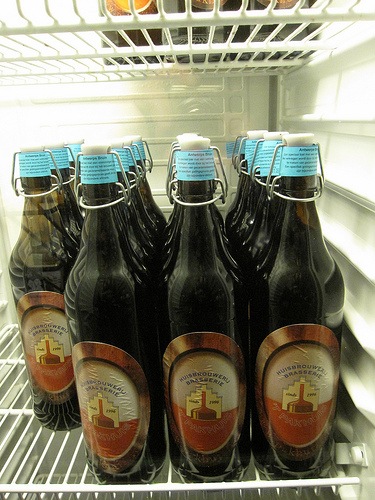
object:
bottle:
[250, 132, 345, 478]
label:
[71, 340, 151, 477]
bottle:
[155, 136, 251, 482]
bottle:
[41, 139, 84, 244]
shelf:
[0, 324, 362, 500]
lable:
[280, 146, 319, 178]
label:
[254, 324, 340, 462]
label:
[15, 290, 75, 405]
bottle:
[8, 146, 83, 431]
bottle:
[64, 144, 167, 484]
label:
[163, 331, 247, 469]